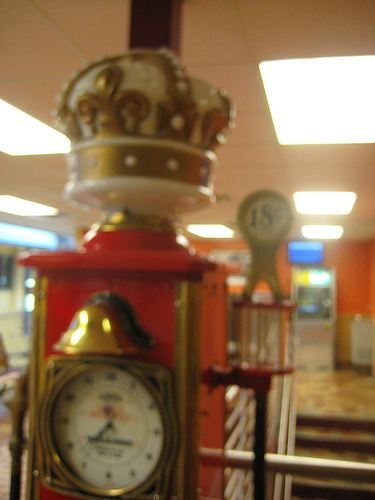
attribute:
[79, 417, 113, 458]
hands — black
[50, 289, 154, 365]
bell — gold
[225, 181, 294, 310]
sign — gold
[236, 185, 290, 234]
number — eighteen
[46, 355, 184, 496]
numbers — black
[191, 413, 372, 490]
railing — thin, silver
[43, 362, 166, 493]
clock — white, black and white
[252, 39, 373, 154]
light — red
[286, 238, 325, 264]
monitor screen — blue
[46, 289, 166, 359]
bell — gold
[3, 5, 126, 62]
tile — white, beige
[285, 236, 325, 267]
sign — blue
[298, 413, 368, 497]
staircase — downstairs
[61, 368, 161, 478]
numbers — black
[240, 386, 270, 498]
pole — black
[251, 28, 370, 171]
lights — on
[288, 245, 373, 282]
wall — orange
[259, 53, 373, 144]
light fixture — large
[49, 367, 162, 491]
face — blurry